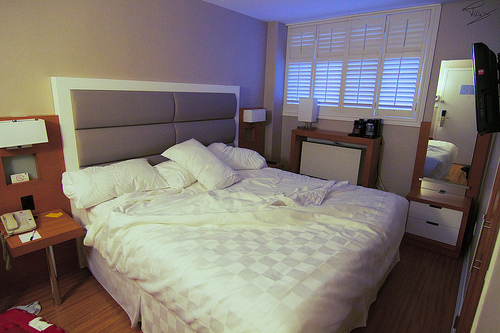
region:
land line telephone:
[1, 207, 38, 242]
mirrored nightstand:
[403, 56, 495, 261]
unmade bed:
[48, 72, 411, 332]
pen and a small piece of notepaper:
[17, 226, 44, 244]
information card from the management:
[8, 169, 31, 185]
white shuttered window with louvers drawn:
[278, 1, 443, 126]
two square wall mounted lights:
[0, 103, 270, 285]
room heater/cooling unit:
[295, 136, 365, 186]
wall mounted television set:
[466, 40, 493, 135]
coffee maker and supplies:
[344, 116, 383, 141]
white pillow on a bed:
[56, 153, 156, 210]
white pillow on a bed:
[150, 154, 195, 191]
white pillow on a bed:
[152, 138, 241, 195]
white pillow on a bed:
[207, 135, 269, 173]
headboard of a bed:
[47, 68, 250, 168]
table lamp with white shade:
[289, 91, 324, 135]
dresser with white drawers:
[395, 191, 478, 249]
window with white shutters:
[276, 5, 442, 122]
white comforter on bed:
[69, 145, 413, 331]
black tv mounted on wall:
[464, 43, 499, 149]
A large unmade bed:
[55, 140, 411, 329]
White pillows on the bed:
[59, 133, 273, 208]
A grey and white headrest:
[47, 72, 242, 173]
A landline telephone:
[3, 207, 40, 235]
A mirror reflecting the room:
[408, 55, 481, 215]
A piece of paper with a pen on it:
[17, 223, 42, 243]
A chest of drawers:
[402, 189, 470, 264]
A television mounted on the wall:
[463, 39, 498, 139]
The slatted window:
[278, 3, 441, 128]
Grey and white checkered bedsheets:
[100, 204, 377, 331]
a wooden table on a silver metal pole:
[0, 204, 84, 306]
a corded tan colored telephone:
[0, 207, 38, 272]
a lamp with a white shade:
[297, 95, 317, 131]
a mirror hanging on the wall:
[416, 59, 478, 201]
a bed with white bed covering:
[49, 75, 409, 330]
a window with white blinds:
[280, 6, 432, 125]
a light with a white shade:
[0, 114, 47, 152]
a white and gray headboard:
[50, 75, 237, 169]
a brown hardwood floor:
[3, 239, 465, 331]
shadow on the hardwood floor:
[58, 270, 90, 306]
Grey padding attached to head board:
[66, 87, 240, 164]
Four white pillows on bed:
[61, 131, 274, 207]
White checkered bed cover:
[79, 170, 412, 329]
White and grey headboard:
[48, 67, 241, 177]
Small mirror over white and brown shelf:
[418, 57, 481, 202]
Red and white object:
[2, 304, 72, 331]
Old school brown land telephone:
[0, 200, 37, 272]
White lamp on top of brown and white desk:
[293, 94, 322, 131]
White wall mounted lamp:
[0, 115, 52, 155]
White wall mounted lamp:
[239, 107, 271, 129]